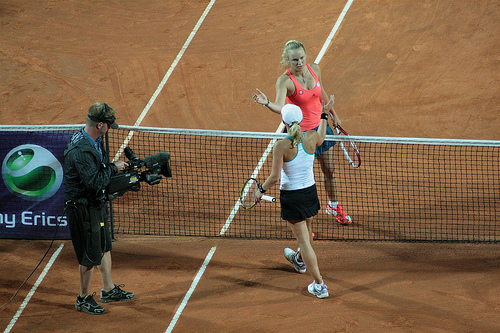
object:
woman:
[249, 38, 354, 230]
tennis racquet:
[327, 110, 360, 166]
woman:
[258, 96, 336, 300]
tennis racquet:
[236, 176, 276, 209]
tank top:
[283, 62, 322, 131]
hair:
[279, 40, 308, 68]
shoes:
[324, 199, 349, 225]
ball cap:
[279, 104, 304, 124]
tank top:
[273, 130, 317, 192]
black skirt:
[276, 185, 320, 222]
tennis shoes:
[281, 245, 308, 273]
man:
[63, 102, 135, 315]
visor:
[90, 108, 120, 133]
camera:
[90, 147, 173, 199]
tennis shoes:
[74, 293, 106, 315]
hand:
[111, 159, 131, 171]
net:
[1, 123, 500, 244]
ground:
[2, 0, 500, 332]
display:
[1, 130, 95, 239]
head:
[83, 102, 121, 138]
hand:
[252, 86, 269, 104]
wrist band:
[320, 115, 330, 120]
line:
[127, 0, 218, 126]